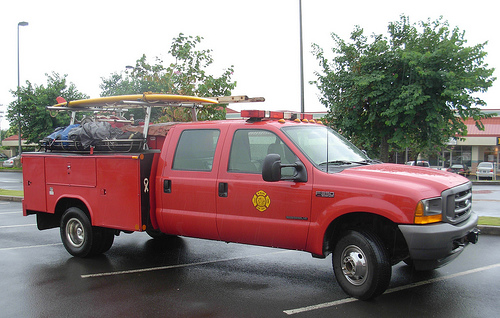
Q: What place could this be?
A: It is a parking lot.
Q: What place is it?
A: It is a parking lot.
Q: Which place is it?
A: It is a parking lot.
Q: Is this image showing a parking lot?
A: Yes, it is showing a parking lot.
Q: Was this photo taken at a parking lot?
A: Yes, it was taken in a parking lot.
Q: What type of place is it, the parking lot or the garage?
A: It is the parking lot.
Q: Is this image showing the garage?
A: No, the picture is showing the parking lot.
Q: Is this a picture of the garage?
A: No, the picture is showing the parking lot.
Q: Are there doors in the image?
A: Yes, there is a door.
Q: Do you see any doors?
A: Yes, there is a door.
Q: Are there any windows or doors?
A: Yes, there is a door.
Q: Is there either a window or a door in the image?
A: Yes, there is a door.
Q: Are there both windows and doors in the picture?
A: Yes, there are both a door and a window.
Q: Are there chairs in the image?
A: No, there are no chairs.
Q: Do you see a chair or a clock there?
A: No, there are no chairs or clocks.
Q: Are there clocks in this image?
A: No, there are no clocks.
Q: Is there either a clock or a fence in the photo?
A: No, there are no clocks or fences.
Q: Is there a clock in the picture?
A: No, there are no clocks.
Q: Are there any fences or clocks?
A: No, there are no clocks or fences.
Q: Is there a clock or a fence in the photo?
A: No, there are no clocks or fences.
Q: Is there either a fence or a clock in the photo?
A: No, there are no clocks or fences.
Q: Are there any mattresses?
A: No, there are no mattresses.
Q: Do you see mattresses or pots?
A: No, there are no mattresses or pots.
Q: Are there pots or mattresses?
A: No, there are no mattresses or pots.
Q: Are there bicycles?
A: No, there are no bicycles.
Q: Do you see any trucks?
A: Yes, there is a truck.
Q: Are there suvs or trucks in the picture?
A: Yes, there is a truck.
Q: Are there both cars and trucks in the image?
A: Yes, there are both a truck and cars.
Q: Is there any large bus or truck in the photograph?
A: Yes, there is a large truck.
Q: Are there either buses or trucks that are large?
A: Yes, the truck is large.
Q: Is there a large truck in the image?
A: Yes, there is a large truck.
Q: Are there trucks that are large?
A: Yes, there is a truck that is large.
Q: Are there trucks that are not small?
A: Yes, there is a large truck.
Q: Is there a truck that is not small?
A: Yes, there is a large truck.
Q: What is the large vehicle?
A: The vehicle is a truck.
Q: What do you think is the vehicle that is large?
A: The vehicle is a truck.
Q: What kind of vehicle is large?
A: The vehicle is a truck.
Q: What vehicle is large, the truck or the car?
A: The truck is large.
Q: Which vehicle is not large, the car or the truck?
A: The car is not large.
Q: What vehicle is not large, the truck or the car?
A: The car is not large.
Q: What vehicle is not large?
A: The vehicle is a car.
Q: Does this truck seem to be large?
A: Yes, the truck is large.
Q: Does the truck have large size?
A: Yes, the truck is large.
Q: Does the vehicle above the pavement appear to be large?
A: Yes, the truck is large.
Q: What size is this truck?
A: The truck is large.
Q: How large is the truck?
A: The truck is large.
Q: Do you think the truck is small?
A: No, the truck is large.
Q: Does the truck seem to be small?
A: No, the truck is large.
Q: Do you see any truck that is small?
A: No, there is a truck but it is large.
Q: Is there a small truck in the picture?
A: No, there is a truck but it is large.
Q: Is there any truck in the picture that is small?
A: No, there is a truck but it is large.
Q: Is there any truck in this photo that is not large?
A: No, there is a truck but it is large.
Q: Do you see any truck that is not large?
A: No, there is a truck but it is large.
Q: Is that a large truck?
A: Yes, that is a large truck.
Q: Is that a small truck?
A: No, that is a large truck.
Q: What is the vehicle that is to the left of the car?
A: The vehicle is a truck.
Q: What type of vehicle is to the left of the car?
A: The vehicle is a truck.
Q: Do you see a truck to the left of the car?
A: Yes, there is a truck to the left of the car.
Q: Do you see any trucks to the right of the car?
A: No, the truck is to the left of the car.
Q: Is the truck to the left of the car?
A: Yes, the truck is to the left of the car.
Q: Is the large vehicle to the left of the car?
A: Yes, the truck is to the left of the car.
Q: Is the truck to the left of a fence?
A: No, the truck is to the left of the car.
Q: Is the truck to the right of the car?
A: No, the truck is to the left of the car.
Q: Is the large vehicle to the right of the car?
A: No, the truck is to the left of the car.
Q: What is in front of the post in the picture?
A: The truck is in front of the post.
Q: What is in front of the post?
A: The truck is in front of the post.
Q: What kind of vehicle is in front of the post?
A: The vehicle is a truck.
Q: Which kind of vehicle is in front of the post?
A: The vehicle is a truck.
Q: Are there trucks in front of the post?
A: Yes, there is a truck in front of the post.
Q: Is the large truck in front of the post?
A: Yes, the truck is in front of the post.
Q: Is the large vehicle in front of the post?
A: Yes, the truck is in front of the post.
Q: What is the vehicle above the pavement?
A: The vehicle is a truck.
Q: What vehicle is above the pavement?
A: The vehicle is a truck.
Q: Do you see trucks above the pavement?
A: Yes, there is a truck above the pavement.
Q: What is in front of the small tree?
A: The truck is in front of the tree.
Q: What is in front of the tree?
A: The truck is in front of the tree.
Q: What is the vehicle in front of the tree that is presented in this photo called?
A: The vehicle is a truck.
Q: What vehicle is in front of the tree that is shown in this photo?
A: The vehicle is a truck.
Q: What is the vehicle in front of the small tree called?
A: The vehicle is a truck.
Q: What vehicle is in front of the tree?
A: The vehicle is a truck.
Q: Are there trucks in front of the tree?
A: Yes, there is a truck in front of the tree.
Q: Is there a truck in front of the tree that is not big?
A: Yes, there is a truck in front of the tree.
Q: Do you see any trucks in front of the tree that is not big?
A: Yes, there is a truck in front of the tree.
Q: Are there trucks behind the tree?
A: No, the truck is in front of the tree.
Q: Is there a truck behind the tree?
A: No, the truck is in front of the tree.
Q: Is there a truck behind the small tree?
A: No, the truck is in front of the tree.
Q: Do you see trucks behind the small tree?
A: No, the truck is in front of the tree.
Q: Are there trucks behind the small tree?
A: No, the truck is in front of the tree.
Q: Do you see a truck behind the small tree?
A: No, the truck is in front of the tree.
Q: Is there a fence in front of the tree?
A: No, there is a truck in front of the tree.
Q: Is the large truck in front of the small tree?
A: Yes, the truck is in front of the tree.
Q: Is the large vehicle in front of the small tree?
A: Yes, the truck is in front of the tree.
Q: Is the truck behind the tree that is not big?
A: No, the truck is in front of the tree.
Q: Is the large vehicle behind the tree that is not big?
A: No, the truck is in front of the tree.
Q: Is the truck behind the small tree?
A: No, the truck is in front of the tree.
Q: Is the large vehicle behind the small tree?
A: No, the truck is in front of the tree.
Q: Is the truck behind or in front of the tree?
A: The truck is in front of the tree.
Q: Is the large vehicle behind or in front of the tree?
A: The truck is in front of the tree.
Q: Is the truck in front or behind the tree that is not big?
A: The truck is in front of the tree.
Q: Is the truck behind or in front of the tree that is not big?
A: The truck is in front of the tree.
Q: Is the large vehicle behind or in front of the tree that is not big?
A: The truck is in front of the tree.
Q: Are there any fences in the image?
A: No, there are no fences.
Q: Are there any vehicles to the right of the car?
A: No, the vehicles are to the left of the car.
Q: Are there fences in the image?
A: No, there are no fences.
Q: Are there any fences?
A: No, there are no fences.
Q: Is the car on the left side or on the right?
A: The car is on the right of the image.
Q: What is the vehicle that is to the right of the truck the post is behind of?
A: The vehicle is a car.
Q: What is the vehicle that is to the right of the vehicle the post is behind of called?
A: The vehicle is a car.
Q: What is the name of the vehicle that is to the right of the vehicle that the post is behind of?
A: The vehicle is a car.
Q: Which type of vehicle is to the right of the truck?
A: The vehicle is a car.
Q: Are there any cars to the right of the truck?
A: Yes, there is a car to the right of the truck.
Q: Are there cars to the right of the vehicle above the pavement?
A: Yes, there is a car to the right of the truck.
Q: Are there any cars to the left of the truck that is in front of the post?
A: No, the car is to the right of the truck.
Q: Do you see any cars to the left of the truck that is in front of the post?
A: No, the car is to the right of the truck.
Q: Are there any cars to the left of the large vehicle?
A: No, the car is to the right of the truck.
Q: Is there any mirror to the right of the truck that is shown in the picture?
A: No, there is a car to the right of the truck.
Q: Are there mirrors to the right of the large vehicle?
A: No, there is a car to the right of the truck.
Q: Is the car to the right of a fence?
A: No, the car is to the right of a truck.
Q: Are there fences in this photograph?
A: No, there are no fences.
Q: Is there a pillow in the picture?
A: No, there are no pillows.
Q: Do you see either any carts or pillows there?
A: No, there are no pillows or carts.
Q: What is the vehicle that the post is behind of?
A: The vehicle is a truck.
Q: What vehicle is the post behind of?
A: The post is behind the truck.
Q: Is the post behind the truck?
A: Yes, the post is behind the truck.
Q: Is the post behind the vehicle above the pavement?
A: Yes, the post is behind the truck.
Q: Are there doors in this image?
A: Yes, there is a door.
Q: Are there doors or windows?
A: Yes, there is a door.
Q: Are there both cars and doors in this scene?
A: Yes, there are both a door and a car.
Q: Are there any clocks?
A: No, there are no clocks.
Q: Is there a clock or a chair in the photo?
A: No, there are no clocks or chairs.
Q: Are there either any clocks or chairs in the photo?
A: No, there are no clocks or chairs.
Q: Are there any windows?
A: Yes, there is a window.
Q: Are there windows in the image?
A: Yes, there is a window.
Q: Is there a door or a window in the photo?
A: Yes, there is a window.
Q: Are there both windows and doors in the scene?
A: Yes, there are both a window and a door.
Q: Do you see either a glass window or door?
A: Yes, there is a glass window.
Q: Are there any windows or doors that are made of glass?
A: Yes, the window is made of glass.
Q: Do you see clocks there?
A: No, there are no clocks.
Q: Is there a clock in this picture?
A: No, there are no clocks.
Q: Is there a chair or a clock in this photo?
A: No, there are no clocks or chairs.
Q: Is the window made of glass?
A: Yes, the window is made of glass.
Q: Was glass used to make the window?
A: Yes, the window is made of glass.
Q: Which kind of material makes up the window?
A: The window is made of glass.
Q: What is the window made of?
A: The window is made of glass.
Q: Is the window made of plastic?
A: No, the window is made of glass.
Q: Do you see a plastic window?
A: No, there is a window but it is made of glass.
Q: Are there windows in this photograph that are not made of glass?
A: No, there is a window but it is made of glass.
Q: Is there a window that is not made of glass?
A: No, there is a window but it is made of glass.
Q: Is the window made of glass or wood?
A: The window is made of glass.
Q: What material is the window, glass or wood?
A: The window is made of glass.